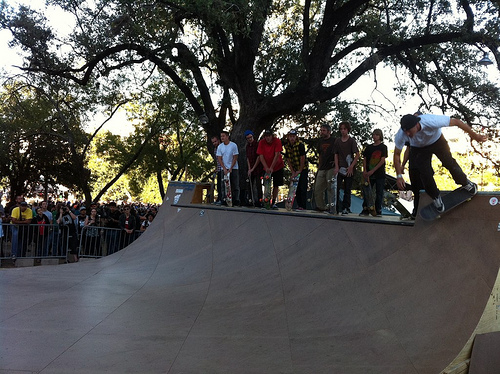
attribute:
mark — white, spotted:
[484, 194, 495, 212]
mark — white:
[487, 193, 494, 222]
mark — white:
[486, 196, 497, 215]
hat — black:
[400, 112, 419, 126]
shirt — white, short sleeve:
[408, 121, 444, 144]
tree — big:
[7, 1, 483, 216]